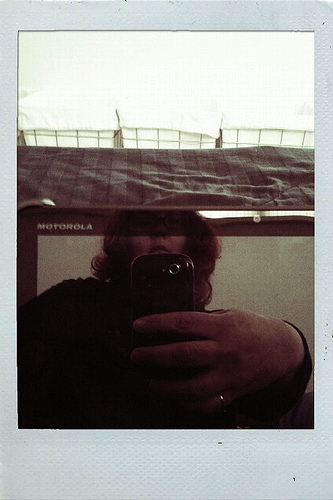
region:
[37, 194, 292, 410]
woman taking a picture with her phone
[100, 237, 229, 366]
black and silver cellphone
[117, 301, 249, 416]
small ring on a pinky finger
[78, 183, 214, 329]
woman with short brown hair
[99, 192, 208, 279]
woman wearing glasses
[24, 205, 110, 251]
a label that says motorola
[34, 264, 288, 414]
woman wearing a black shirt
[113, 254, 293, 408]
hand holding a cellphone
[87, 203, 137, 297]
curly brown hair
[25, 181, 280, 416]
reflection on a cellphone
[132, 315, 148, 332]
the finger nail of a person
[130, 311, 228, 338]
the finger of a person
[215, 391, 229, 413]
a ring on the finger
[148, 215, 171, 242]
the nose of a person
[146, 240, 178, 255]
the mouth of a person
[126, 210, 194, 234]
a pair of glasses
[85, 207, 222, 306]
the head of a person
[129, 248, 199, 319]
the back of a cell phone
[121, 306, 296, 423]
the hand of a person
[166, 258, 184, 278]
the camera of the phone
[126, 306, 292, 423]
the hand of the person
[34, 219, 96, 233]
writing on the screen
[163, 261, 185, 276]
camera on front of phone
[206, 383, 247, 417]
metal ring on finger of person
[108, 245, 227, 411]
person holding black cellphone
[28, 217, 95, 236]
writing on building wall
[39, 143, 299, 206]
striped awning outside building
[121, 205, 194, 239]
pair of eye glasses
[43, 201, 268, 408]
woman taking picture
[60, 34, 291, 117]
sky filled with bright sun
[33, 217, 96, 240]
company name on side of building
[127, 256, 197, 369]
black cellphone being held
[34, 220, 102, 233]
brand of electronic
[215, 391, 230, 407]
ring on person taking the pictures hand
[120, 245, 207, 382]
reflection of cell phone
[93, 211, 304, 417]
reflection of person in electronic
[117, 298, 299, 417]
reflection of a hand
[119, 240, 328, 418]
hand holding a cell phone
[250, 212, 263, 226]
camera spot on tablet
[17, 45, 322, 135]
drapes closed over windows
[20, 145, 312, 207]
striped blanket covering furniture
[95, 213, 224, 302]
reflection of person with glasses